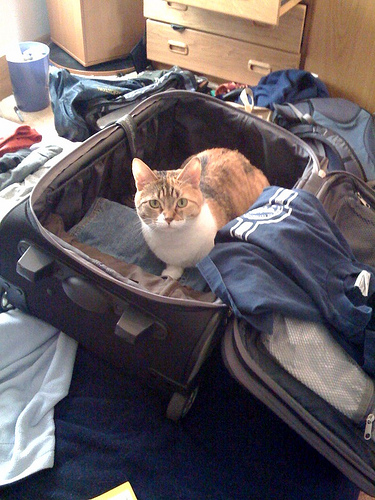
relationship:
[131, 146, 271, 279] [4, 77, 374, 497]
cat in suitcase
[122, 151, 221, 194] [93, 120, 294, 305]
ears on cat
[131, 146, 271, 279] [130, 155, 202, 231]
cat has head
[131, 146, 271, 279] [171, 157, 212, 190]
cat has ear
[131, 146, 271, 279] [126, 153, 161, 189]
cat has ear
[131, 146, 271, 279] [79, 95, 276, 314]
cat inside suitcase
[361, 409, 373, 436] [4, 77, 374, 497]
zipper on suitcase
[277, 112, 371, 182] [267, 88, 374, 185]
strap on bag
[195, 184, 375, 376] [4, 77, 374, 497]
shirt in suitcase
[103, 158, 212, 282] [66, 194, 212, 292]
cat lying on jeans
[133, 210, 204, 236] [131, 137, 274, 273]
whiskers of cat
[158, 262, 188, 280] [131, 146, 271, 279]
paw of cat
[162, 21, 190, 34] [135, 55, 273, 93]
clothes sticking out drawer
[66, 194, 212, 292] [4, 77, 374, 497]
jeans folded in suitcase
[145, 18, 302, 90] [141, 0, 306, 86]
drawer of drawers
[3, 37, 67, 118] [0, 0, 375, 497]
trashcan in bureau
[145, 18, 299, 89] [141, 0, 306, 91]
drawer to bureau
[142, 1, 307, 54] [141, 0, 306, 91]
drawer to bureau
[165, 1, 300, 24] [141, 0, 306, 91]
drawer to bureau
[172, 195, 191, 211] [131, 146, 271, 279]
eye of cat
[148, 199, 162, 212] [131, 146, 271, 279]
eye of cat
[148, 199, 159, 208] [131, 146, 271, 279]
eye of cat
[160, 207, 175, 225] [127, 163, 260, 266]
nose of cat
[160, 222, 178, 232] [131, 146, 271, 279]
mouth of cat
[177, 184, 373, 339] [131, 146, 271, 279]
shirt near cat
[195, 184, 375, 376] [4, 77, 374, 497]
shirt near suitcase